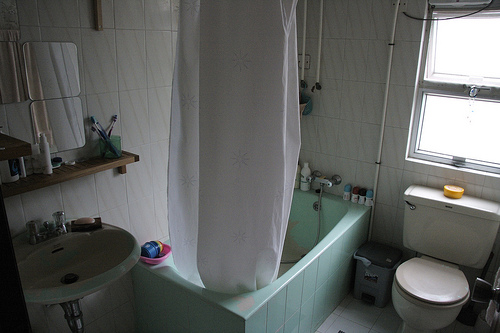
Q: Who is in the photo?
A: Nobody.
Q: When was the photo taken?
A: Daytime.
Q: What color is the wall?
A: White.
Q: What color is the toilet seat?
A: White.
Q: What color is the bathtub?
A: Blue.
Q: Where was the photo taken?
A: In the bathroom.